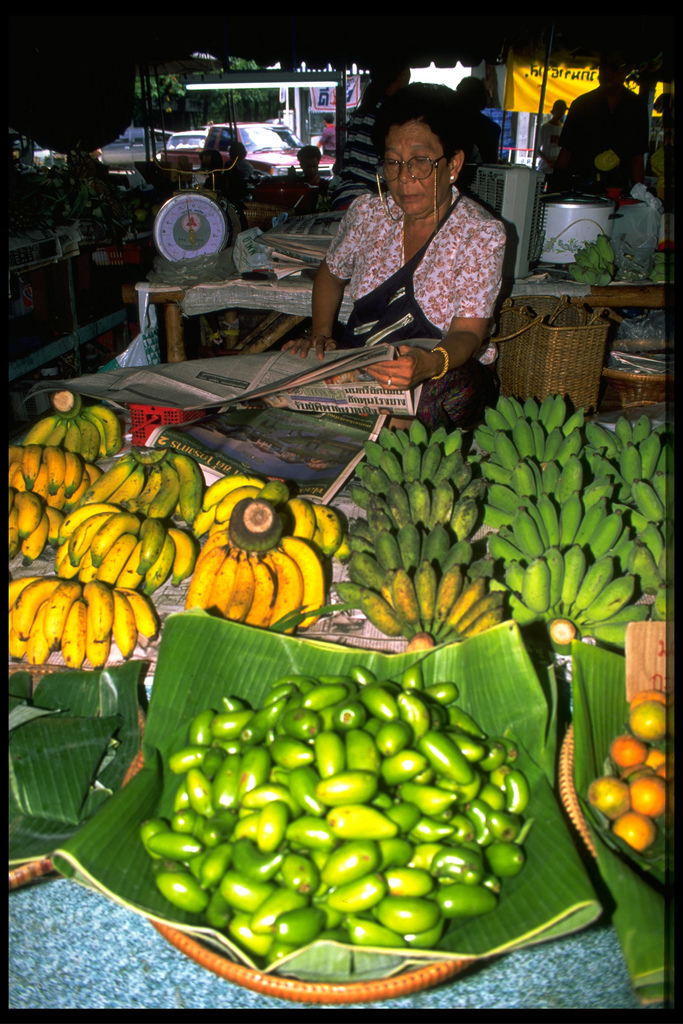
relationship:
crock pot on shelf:
[526, 184, 622, 271] [115, 247, 676, 377]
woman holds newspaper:
[281, 42, 507, 453] [28, 339, 443, 422]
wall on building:
[76, 165, 160, 258] [9, 3, 678, 1010]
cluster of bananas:
[6, 392, 351, 672] [122, 471, 231, 665]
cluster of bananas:
[6, 392, 329, 651] [483, 465, 615, 627]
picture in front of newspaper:
[274, 358, 396, 456] [28, 339, 443, 423]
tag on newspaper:
[217, 355, 311, 438] [28, 339, 443, 422]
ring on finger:
[384, 344, 407, 473] [360, 368, 405, 389]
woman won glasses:
[281, 80, 507, 453] [331, 123, 470, 288]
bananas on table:
[199, 463, 566, 638] [9, 391, 680, 1009]